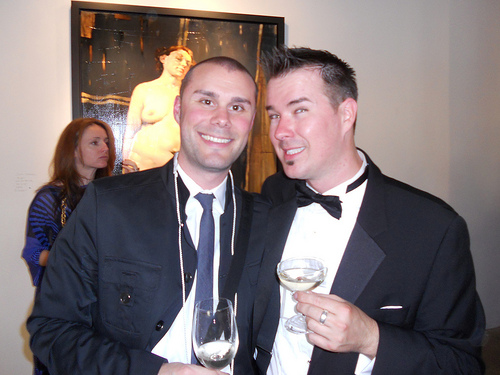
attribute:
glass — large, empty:
[194, 297, 241, 371]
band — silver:
[319, 309, 329, 325]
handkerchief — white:
[150, 262, 199, 363]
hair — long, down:
[35, 118, 117, 212]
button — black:
[155, 320, 165, 332]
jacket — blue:
[26, 160, 271, 375]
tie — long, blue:
[194, 191, 217, 366]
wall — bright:
[0, 1, 499, 375]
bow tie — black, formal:
[295, 182, 342, 219]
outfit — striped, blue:
[23, 178, 99, 286]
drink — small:
[275, 258, 326, 334]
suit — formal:
[251, 146, 487, 374]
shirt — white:
[265, 149, 369, 375]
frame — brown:
[71, 1, 284, 195]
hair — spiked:
[263, 46, 357, 113]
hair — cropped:
[181, 55, 259, 107]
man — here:
[251, 45, 488, 375]